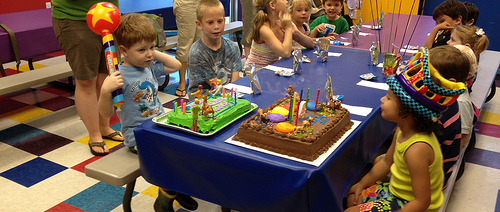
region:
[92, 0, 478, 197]
children sitting at table with blue tablecloth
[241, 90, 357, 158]
cake with chocolate icing on table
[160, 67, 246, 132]
cake with green icing on table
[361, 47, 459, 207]
child wearing yellow shirt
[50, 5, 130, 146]
person wearing green shirt standing up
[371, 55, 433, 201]
child wearing party hat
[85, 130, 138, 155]
flip flops of person wearing green shirt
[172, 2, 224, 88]
person wearing khaki shorts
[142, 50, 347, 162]
two cakes on table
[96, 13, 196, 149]
child sitting in front of cake with green icing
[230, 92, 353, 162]
A large chocolate cake.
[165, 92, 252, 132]
A small green cake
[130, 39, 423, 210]
A table with blue table cloth.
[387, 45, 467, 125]
A colorful hat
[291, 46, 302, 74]
A juice pouch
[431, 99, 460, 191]
A stripped shirt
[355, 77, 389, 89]
A peice of white paper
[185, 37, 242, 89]
A grey tee shirt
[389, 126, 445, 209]
A yellow tank top.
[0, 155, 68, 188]
A blue square on the floor.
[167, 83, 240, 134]
Green birthday cake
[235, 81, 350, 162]
A chocolate birthday cake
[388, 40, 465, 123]
A multicolor birthday hat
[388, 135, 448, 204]
A yellow tee shirt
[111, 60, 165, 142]
A blue tee shirt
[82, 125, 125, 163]
Brown flip flops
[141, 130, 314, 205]
A blue table cloth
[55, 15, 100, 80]
Dark brown shorts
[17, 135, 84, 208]
White, red, blue and brown floor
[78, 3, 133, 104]
Red, yellow, dark blue and light toy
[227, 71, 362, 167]
cake with brown icing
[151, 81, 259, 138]
cake with green icing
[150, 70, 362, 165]
two cakes with decorations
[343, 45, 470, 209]
child wearing a colorful crown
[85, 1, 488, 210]
children attending a party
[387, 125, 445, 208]
bright yellow tank top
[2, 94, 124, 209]
multi-colored square tiled flooring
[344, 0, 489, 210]
seated row of children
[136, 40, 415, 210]
blue picnic tablecloth under two cakes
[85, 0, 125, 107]
large colorful toy with a star design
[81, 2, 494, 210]
Child's birthday party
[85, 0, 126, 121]
Blow up toy wand for a boy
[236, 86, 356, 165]
Brown frosted birthday cake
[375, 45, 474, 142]
Child with a blown up crown on head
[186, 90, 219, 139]
Figurines for a birthday cake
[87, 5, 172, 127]
Birthday boy with blow up wand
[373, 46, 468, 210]
Birthday boy with crown on head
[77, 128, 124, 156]
Brown sandles on a women's feet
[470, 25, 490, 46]
Flower in a ponytail